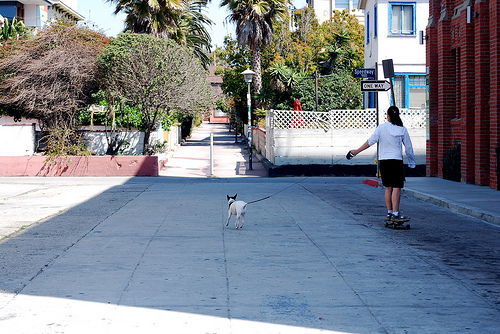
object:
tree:
[301, 8, 363, 80]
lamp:
[236, 67, 253, 90]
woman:
[354, 102, 417, 234]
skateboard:
[377, 209, 409, 230]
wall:
[417, 12, 499, 196]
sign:
[354, 76, 390, 96]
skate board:
[378, 200, 419, 226]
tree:
[1, 23, 111, 155]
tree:
[92, 32, 214, 155]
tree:
[218, 0, 289, 124]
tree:
[113, 0, 186, 46]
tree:
[305, 7, 367, 77]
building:
[424, 1, 499, 189]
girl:
[349, 106, 433, 234]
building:
[363, 0, 430, 109]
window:
[391, 2, 413, 34]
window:
[394, 76, 404, 108]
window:
[407, 84, 430, 109]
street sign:
[354, 58, 392, 93]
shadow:
[4, 172, 495, 320]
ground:
[1, 178, 493, 333]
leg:
[381, 185, 391, 212]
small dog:
[205, 187, 276, 237]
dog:
[217, 190, 252, 234]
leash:
[231, 120, 376, 200]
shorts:
[378, 157, 405, 187]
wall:
[0, 152, 160, 178]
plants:
[0, 17, 223, 154]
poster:
[244, 97, 254, 107]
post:
[240, 85, 257, 172]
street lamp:
[230, 61, 259, 176]